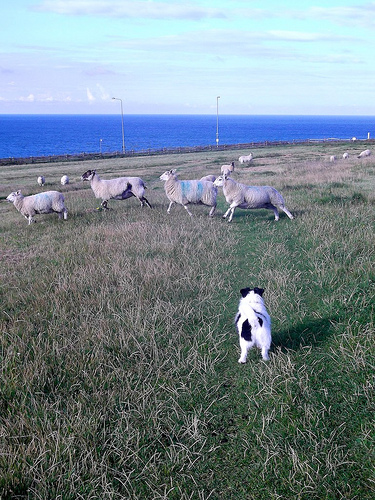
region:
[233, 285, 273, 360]
a sheep dog watches a flock of sheep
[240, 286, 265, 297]
the dog has black ears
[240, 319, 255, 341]
the dog has a black spot near his white tail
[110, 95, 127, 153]
there are tall streetlights near the water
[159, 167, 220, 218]
there are blue marks on a sheep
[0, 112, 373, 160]
the water is bright blue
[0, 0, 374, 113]
the sky is light blue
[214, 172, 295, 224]
there is a sheep behind a sheep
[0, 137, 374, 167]
there is a wooden fence near the water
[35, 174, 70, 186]
there are a couple of sheep in the distance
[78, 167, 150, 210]
sheep with black face running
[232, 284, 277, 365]
dog herding the sheep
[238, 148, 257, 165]
sheep in background looking right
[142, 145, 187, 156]
fence in background to keep sheep enclosed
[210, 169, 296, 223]
white sheep running to the left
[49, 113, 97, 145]
body of water behind running sheep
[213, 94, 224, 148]
street light behind field of sheep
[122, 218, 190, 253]
grass the sheep are running through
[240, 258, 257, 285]
green grass in front of herding dog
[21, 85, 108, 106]
clouds over the water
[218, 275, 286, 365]
black and white dog in the green grass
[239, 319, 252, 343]
black spot on the dog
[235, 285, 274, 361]
black and white dog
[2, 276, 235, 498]
mix of dead and green grass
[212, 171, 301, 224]
sheep on the grass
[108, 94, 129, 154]
tall lamp post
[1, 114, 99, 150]
blue water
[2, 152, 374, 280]
field of sheep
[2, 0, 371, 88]
clouds in the blue sky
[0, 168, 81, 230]
three white sheep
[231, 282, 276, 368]
a black and white dog in the field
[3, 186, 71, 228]
a sheep in the field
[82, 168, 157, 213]
a sheep in the field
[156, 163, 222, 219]
a sheep in the field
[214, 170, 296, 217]
a sheep in the field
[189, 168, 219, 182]
a sheep in the field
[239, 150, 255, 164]
a sheep in the field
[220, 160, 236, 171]
a sheep in the field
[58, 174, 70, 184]
a sheep in the field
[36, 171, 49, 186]
a sheep in the field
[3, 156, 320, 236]
Sheep walking in a field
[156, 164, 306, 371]
Border collie watching sheep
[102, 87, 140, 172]
A street light at side of road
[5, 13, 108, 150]
Bright blue ocean water and partly cloudy sky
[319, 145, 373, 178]
Sheep grazing in a field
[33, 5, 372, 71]
Thin grey clouds against an aqua color sky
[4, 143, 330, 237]
Small herd of sheep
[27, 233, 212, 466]
Dry looking, brown grass field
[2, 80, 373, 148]
View of horizon over water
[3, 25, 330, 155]
View from the coast looking out over water